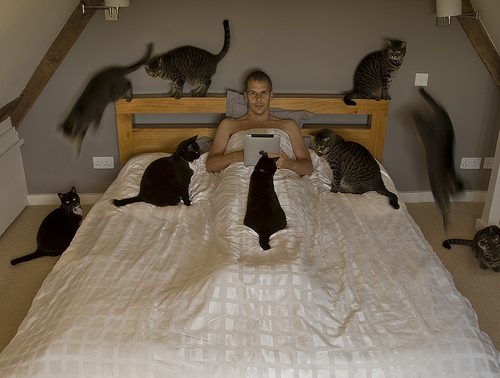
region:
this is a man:
[215, 73, 287, 157]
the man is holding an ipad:
[240, 130, 280, 154]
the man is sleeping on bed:
[219, 75, 299, 155]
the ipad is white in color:
[243, 128, 281, 149]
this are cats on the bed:
[154, 147, 289, 242]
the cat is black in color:
[134, 132, 200, 204]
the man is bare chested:
[217, 117, 292, 129]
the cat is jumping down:
[406, 93, 459, 204]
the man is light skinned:
[257, 82, 265, 86]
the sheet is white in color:
[56, 258, 416, 370]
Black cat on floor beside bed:
[29, 175, 109, 285]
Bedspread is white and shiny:
[140, 221, 333, 356]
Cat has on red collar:
[240, 152, 262, 184]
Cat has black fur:
[230, 156, 286, 289]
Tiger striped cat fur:
[301, 125, 391, 263]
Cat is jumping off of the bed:
[400, 61, 487, 252]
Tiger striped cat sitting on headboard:
[344, 39, 406, 122]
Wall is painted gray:
[409, 37, 459, 130]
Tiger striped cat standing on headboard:
[136, 39, 225, 123]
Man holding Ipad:
[221, 102, 307, 212]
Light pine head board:
[114, 94, 220, 148]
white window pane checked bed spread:
[82, 225, 449, 373]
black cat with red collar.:
[224, 141, 301, 274]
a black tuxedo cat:
[11, 163, 102, 287]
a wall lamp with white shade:
[411, 0, 484, 41]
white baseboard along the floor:
[26, 177, 102, 216]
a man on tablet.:
[234, 60, 299, 187]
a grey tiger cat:
[308, 119, 400, 215]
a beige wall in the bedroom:
[163, 10, 393, 89]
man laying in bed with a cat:
[217, 71, 312, 191]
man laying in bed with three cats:
[236, 30, 448, 266]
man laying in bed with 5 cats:
[137, 26, 417, 248]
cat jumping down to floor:
[408, 74, 476, 239]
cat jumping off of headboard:
[48, 43, 148, 182]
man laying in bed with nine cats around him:
[6, 5, 499, 275]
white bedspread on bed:
[75, 239, 469, 358]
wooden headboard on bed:
[108, 94, 213, 148]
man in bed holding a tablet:
[223, 73, 306, 165]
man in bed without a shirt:
[220, 72, 310, 177]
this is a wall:
[249, 12, 355, 58]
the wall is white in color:
[248, 15, 336, 61]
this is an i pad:
[240, 131, 283, 167]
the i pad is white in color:
[246, 139, 255, 166]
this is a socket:
[90, 154, 117, 173]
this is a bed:
[121, 97, 385, 376]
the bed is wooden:
[116, 125, 171, 151]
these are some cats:
[31, 49, 498, 259]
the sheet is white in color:
[119, 217, 201, 360]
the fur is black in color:
[149, 163, 178, 197]